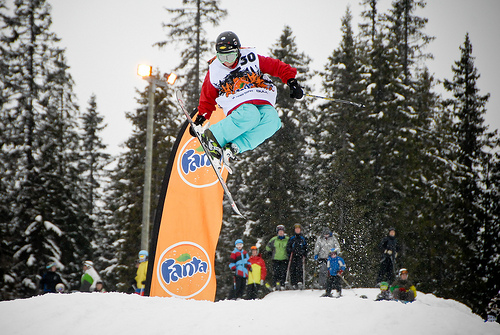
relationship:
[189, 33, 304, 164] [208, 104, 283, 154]
person wearing pants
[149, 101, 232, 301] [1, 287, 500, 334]
banner on slope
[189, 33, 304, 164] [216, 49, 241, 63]
person wearing goggles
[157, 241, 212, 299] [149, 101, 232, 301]
logo on banner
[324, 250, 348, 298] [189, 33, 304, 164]
spectator watching person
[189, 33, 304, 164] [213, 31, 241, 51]
person wearing a helmet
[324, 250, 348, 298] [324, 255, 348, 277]
spectator wearing jacket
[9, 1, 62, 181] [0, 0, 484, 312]
tree standing in background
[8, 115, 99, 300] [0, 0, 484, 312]
tree standing in background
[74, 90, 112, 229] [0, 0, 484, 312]
tree standing in background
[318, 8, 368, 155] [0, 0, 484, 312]
tree standing in background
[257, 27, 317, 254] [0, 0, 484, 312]
tree standing in background